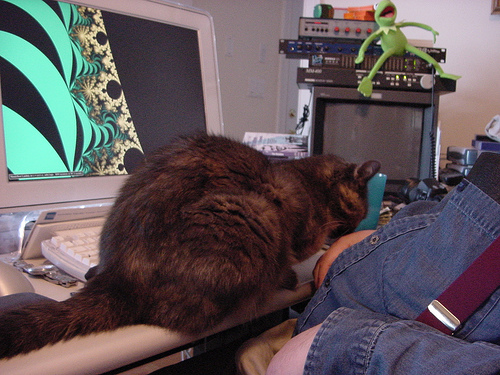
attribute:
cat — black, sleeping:
[5, 130, 375, 329]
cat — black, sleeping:
[2, 126, 384, 360]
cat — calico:
[1, 111, 408, 327]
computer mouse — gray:
[1, 257, 36, 304]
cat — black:
[57, 109, 381, 329]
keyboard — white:
[41, 223, 111, 279]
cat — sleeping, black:
[13, 129, 385, 345]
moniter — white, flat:
[13, 7, 247, 231]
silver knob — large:
[418, 73, 435, 89]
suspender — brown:
[417, 233, 499, 339]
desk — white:
[4, 330, 239, 372]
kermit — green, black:
[360, 1, 459, 93]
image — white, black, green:
[1, 1, 146, 171]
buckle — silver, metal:
[425, 296, 466, 336]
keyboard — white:
[37, 221, 105, 278]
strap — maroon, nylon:
[428, 239, 498, 326]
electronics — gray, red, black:
[294, 13, 399, 43]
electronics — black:
[274, 33, 396, 62]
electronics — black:
[304, 49, 451, 74]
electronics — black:
[295, 65, 459, 99]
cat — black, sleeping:
[109, 135, 386, 320]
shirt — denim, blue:
[292, 182, 495, 372]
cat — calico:
[94, 142, 375, 328]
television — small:
[301, 86, 437, 190]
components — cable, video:
[273, 11, 460, 96]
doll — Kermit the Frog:
[352, 2, 463, 99]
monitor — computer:
[13, 34, 291, 196]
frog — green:
[355, 0, 455, 101]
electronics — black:
[271, 10, 461, 97]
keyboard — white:
[44, 226, 114, 284]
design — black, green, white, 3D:
[0, 6, 150, 178]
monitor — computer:
[1, 0, 255, 255]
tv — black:
[305, 86, 442, 199]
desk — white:
[2, 245, 327, 371]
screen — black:
[6, 1, 295, 251]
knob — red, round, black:
[333, 27, 341, 33]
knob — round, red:
[344, 26, 351, 34]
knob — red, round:
[356, 26, 362, 32]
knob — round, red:
[366, 29, 372, 34]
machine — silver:
[296, 15, 378, 40]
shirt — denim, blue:
[328, 203, 490, 368]